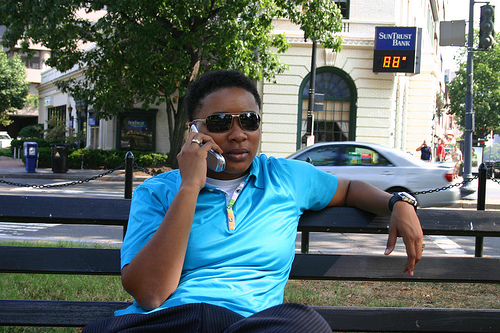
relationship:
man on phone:
[83, 67, 420, 331] [189, 123, 226, 172]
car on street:
[267, 140, 458, 208] [4, 181, 499, 254]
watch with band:
[387, 191, 419, 211] [386, 190, 394, 220]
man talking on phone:
[120, 73, 422, 331] [186, 121, 223, 174]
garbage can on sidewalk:
[46, 143, 70, 176] [0, 138, 499, 188]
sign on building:
[368, 20, 423, 81] [23, 0, 452, 190]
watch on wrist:
[387, 182, 424, 209] [378, 181, 441, 282]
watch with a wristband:
[387, 191, 419, 211] [374, 182, 404, 217]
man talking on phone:
[83, 67, 420, 331] [188, 125, 227, 171]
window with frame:
[293, 64, 357, 146] [298, 62, 358, 152]